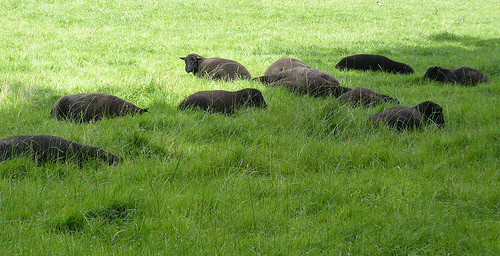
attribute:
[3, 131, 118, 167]
animal — black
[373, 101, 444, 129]
animal — hiding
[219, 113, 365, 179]
grassy area — tall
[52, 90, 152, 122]
animal — laying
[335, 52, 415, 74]
animal — black, laying down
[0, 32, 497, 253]
shadow — cast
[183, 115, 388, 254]
grass — green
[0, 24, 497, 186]
animals — laying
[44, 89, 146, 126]
animal — laying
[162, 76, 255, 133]
animal — dark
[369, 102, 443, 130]
animal — dark gray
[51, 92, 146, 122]
animal — black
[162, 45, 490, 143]
animals — laying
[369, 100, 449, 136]
animal — black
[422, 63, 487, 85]
animal — black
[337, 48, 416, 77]
animal — black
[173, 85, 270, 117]
animal — black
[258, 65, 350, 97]
animal — black, laying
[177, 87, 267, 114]
sheep — black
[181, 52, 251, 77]
sheep — black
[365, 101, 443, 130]
sheep — black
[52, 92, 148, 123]
sheep — black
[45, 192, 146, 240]
area — dark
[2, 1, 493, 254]
field — grassy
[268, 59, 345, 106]
animal — lying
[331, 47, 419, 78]
animal — lying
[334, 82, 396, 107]
animal — black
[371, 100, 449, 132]
animal — black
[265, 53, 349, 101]
animal — laying, black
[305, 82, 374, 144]
grass — tall, clumped